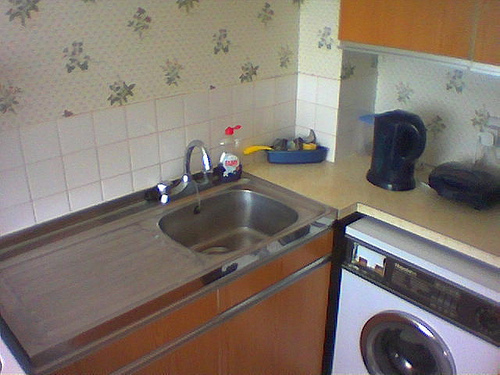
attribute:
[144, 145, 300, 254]
sink — stainless steel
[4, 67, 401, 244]
tile — white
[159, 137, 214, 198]
faucet — silver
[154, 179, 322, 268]
sink — silver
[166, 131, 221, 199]
faucet — silver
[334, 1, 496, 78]
cupboards — brown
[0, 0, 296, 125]
wallpaper — patterned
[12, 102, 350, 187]
tile — white, above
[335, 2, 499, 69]
cabinets — wooden, brown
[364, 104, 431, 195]
tea kettle — black, electric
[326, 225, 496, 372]
washing machine — white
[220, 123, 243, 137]
cap — red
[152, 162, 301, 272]
sink — silver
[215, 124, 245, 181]
soap container — plastic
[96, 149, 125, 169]
tile — white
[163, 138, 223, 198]
faucet — silver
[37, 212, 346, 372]
drawers — wooden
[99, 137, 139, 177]
tile — white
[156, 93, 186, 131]
tile — white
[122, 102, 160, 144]
tile — white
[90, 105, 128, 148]
tile — white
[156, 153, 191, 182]
tile — white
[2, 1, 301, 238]
wall — white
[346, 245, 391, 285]
panel — control